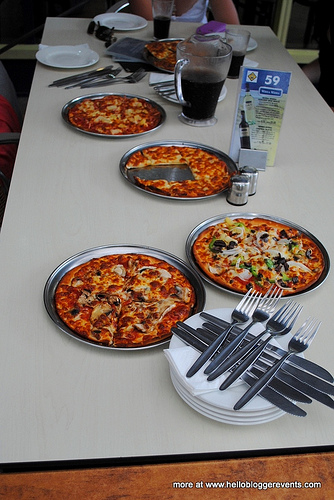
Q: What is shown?
A: Pizza.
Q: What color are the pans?
A: Silver.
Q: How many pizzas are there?
A: 5.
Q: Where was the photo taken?
A: Restaurant.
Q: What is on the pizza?
A: Cheese.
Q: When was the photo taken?
A: Mealtime.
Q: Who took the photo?
A: Patron.